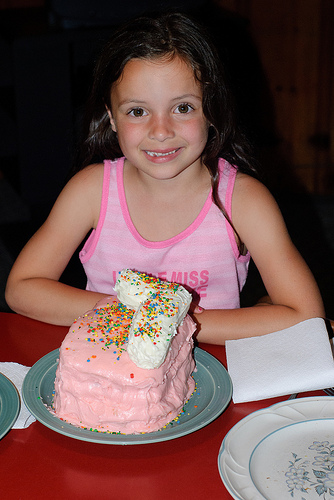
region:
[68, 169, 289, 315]
A girl is wearing a pink shirt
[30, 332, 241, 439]
Pink cake is in a plate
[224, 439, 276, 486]
The plate is white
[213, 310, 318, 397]
The napkin is white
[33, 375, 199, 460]
The plate is green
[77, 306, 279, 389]
the cake is topped with sprinkles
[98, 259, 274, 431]
A 7 made of icing is on the cake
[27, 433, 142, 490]
The table is red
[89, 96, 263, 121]
The girl has brown eyes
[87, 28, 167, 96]
The girl's hair is dark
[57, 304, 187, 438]
a cake with pink frosting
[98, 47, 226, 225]
the girl is smiling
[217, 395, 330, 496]
white china plate with blue flower decoration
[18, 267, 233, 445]
pink cake with sprinkles and a white 7 on top with sprinkles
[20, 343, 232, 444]
gray dinner plate with a pink cake on it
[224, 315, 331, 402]
white folded napkin on a dark orange table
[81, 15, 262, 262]
young girl with long dark brown hair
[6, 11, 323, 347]
little girl with a pink tank top with a cake in front of her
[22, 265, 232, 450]
seven year pink frosted birthday cake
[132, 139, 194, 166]
smile on a young girl probably on her birthday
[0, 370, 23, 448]
part of a gray plate on a dark red table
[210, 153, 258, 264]
long strands of very dark hair on a young girl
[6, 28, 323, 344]
young girl wearing pink tanktop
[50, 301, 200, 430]
cake with pink frosting and sprinkles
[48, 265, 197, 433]
small white cake on larger pink cake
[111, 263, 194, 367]
cake shaped as "7"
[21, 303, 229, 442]
pink cake on blue plate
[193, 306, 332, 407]
white napkin in front of girl's arm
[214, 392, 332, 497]
empty white plate with blue design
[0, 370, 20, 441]
empty blue plate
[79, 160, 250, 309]
pink tanktop with darker pink trim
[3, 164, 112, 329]
girl's right arm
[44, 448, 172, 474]
shiny red surface on the table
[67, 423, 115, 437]
rainbow sprinkles on blue plate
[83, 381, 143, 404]
pink frosting on plate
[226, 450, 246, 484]
wavy pattern on white plate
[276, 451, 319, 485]
flower pattern on white plate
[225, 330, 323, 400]
white paper napkin on table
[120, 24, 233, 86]
curly black hair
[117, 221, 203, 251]
pink edge on pink shirt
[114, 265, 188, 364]
white number on cake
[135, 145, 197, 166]
missing tooth in mouth